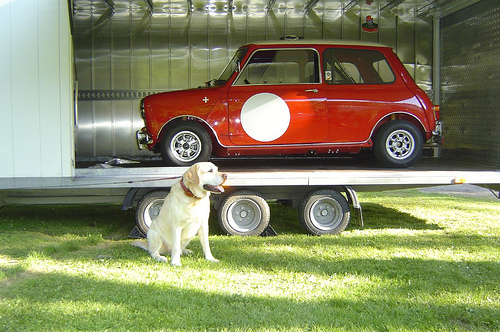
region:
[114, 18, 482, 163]
SMALL RED CAR IN TRAILER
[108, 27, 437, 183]
RED CAR WITH WHITE CIRCLE ON DOOR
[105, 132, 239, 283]
YELLOW LAB PANTING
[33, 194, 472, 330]
SUN AND SHADE ON GRASS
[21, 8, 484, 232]
TRAILER FOR HAULING CARS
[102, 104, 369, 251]
THREE AXELS ON A TRAILER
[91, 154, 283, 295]
DOG OUTSIDE WATCHING OWNERS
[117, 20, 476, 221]
CAR WITH WHITE TOP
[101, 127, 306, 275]
BIG YELLOW LAB SITTING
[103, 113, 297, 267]
YELLOW LAB WITH RED COLLAR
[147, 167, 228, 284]
A white big dog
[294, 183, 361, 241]
A grey truck tyre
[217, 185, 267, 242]
A grey truck tyre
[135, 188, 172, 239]
A grey truck tyre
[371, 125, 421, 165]
A black truck tyre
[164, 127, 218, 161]
A black truck tyre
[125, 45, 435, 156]
A small red car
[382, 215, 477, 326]
A green grass field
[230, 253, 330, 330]
A green grass field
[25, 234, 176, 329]
A green grass field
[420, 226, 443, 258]
green grass on ground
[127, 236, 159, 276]
green grass on ground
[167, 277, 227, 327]
green grass on ground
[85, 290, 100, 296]
green grass on ground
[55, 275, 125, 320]
green grass on ground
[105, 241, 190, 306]
green grass on ground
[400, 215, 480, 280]
green grass on ground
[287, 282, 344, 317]
green grass on ground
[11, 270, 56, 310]
green grass on ground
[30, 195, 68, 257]
green grass on ground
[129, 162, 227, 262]
A dog sitting down.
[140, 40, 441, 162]
A small red car.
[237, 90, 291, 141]
A white circle on the car.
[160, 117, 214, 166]
The front tire on the car.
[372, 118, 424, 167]
The back tire on the car.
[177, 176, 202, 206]
The red collar on the dog.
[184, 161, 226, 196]
The head of the dog.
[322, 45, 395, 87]
The rear window on the car.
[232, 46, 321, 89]
The front side window on the car.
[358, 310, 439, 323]
Part of the grass.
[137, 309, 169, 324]
shadow on the grass.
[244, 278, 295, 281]
grass on the ground.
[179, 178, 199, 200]
collar on the dog.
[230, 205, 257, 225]
hubcap on the tire.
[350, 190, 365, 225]
mud flap near the tire.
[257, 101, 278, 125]
white circle on the car.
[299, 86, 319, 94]
handle on the car door.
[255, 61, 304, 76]
window on the car.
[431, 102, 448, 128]
tail light on the car.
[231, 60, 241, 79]
mirror on the car.